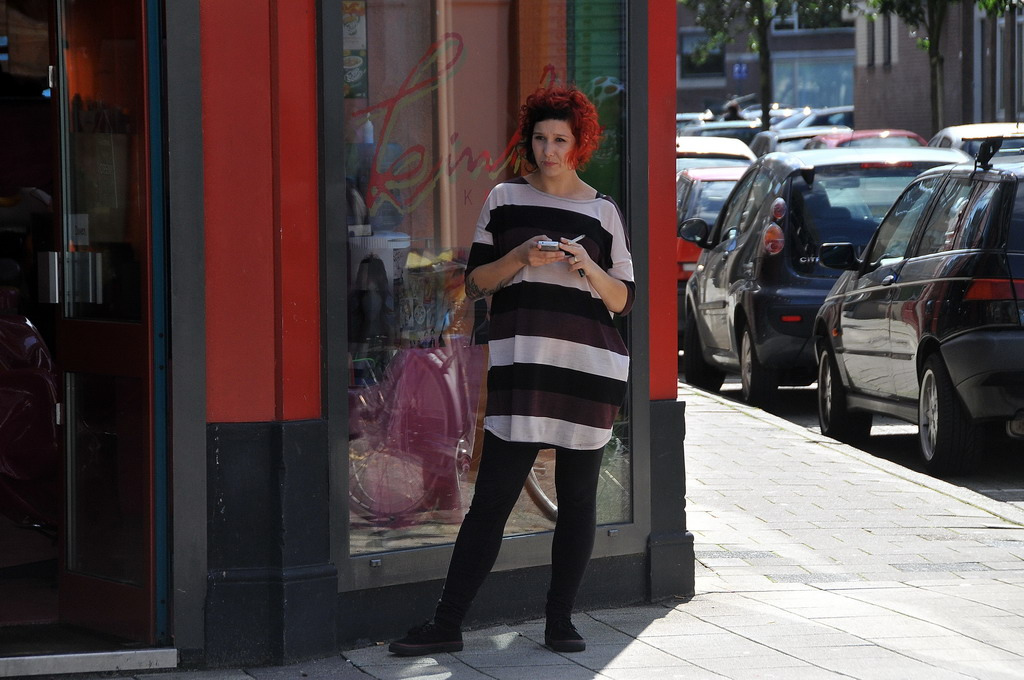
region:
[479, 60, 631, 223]
face of the girl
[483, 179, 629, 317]
hand of the girl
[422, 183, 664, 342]
a phone in the hand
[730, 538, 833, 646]
a view of lines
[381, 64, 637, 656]
the woman is standing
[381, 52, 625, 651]
the woman is smoking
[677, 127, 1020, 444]
the cars are parked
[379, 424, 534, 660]
the leg of the woman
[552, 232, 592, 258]
the cigarette between the fingers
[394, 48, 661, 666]
the woman has red hair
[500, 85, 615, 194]
the head of the woman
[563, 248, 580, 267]
the ring on the finger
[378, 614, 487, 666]
the shoe is black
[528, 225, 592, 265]
The woman is holding cigarette in hand.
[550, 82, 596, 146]
The hair is red.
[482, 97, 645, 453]
The woman is smoking.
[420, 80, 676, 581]
The woman is standing in front of window.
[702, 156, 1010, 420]
Cars parked on side of the road.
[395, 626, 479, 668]
The shoe is black.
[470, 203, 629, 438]
The shirt has stripes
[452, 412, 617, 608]
The woman is wearing black tights.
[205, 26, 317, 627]
The wall is red and black.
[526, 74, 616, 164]
a woman with red hair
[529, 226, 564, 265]
a woman holding a cell phone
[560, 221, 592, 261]
a woman holding a cigarette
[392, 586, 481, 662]
a woman wearing black shoes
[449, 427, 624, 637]
a woman wearing black pants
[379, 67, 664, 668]
a woman standing on a sidewalk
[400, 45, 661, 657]
a woman standing in front of a building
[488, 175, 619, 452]
a woman wearing a striped shirt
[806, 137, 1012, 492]
a car parked next to a curb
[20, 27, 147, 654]
a open glass door with silver handle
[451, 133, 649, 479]
woman wearing a striped shirt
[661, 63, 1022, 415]
a row of cars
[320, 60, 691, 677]
woman standing on the sidewalk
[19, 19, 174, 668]
door on side of the building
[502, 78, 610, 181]
woman has red hair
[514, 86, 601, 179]
the woman's hair is red and black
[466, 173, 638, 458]
the shirt has white, black and brown stripes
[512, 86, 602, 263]
the woman is holding a cigarette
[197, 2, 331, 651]
red and black building exterior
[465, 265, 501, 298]
tattoo on the arm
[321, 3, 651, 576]
woman standing in front of the glass window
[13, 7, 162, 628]
the glass door is opened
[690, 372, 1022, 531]
the curb near the street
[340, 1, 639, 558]
A window on a building.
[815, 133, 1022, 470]
A car on a street.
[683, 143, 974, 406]
A car on a street.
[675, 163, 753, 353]
A car on a street.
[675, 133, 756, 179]
A car on a street.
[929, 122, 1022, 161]
A car on a street.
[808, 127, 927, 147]
A car on a street.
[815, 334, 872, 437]
A tire on a vehicle.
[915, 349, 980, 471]
A tire on a vehicle.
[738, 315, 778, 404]
A tire on a vehicle.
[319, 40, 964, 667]
woman standing up in the background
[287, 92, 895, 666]
woman on the sidewalk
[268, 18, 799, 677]
glass in the window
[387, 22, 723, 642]
woman with red hair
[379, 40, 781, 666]
woman with a striped shirt